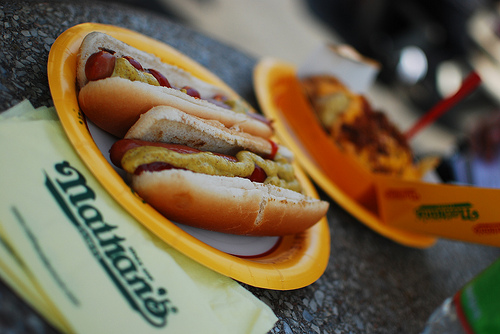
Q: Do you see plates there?
A: Yes, there is a plate.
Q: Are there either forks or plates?
A: Yes, there is a plate.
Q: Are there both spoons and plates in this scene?
A: No, there is a plate but no spoons.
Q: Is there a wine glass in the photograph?
A: No, there are no wine glasses.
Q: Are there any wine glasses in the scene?
A: No, there are no wine glasses.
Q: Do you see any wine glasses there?
A: No, there are no wine glasses.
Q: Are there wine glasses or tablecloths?
A: No, there are no wine glasses or tablecloths.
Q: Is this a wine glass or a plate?
A: This is a plate.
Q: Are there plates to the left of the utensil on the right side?
A: Yes, there is a plate to the left of the fork.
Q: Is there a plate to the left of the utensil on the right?
A: Yes, there is a plate to the left of the fork.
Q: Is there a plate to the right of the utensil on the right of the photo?
A: No, the plate is to the left of the fork.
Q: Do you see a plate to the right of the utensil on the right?
A: No, the plate is to the left of the fork.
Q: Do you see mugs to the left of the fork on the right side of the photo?
A: No, there is a plate to the left of the fork.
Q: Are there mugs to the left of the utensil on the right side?
A: No, there is a plate to the left of the fork.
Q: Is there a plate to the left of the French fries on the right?
A: Yes, there is a plate to the left of the fries.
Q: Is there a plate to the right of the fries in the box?
A: No, the plate is to the left of the French fries.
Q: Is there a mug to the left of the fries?
A: No, there is a plate to the left of the fries.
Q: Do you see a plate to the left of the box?
A: Yes, there is a plate to the left of the box.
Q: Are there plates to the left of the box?
A: Yes, there is a plate to the left of the box.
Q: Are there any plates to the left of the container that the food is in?
A: Yes, there is a plate to the left of the box.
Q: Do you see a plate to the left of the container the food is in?
A: Yes, there is a plate to the left of the box.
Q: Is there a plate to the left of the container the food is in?
A: Yes, there is a plate to the left of the box.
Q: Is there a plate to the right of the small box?
A: No, the plate is to the left of the box.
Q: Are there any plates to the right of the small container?
A: No, the plate is to the left of the box.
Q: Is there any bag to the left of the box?
A: No, there is a plate to the left of the box.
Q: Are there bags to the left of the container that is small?
A: No, there is a plate to the left of the box.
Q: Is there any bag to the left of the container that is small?
A: No, there is a plate to the left of the box.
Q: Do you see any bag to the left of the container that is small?
A: No, there is a plate to the left of the box.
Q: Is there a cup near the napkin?
A: No, there is a plate near the napkin.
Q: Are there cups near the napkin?
A: No, there is a plate near the napkin.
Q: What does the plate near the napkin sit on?
A: The plate sits on the table.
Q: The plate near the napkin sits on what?
A: The plate sits on the table.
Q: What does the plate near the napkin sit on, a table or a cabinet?
A: The plate sits on a table.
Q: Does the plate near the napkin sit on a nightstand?
A: No, the plate sits on the table.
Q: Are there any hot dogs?
A: Yes, there is a hot dog.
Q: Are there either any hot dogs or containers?
A: Yes, there is a hot dog.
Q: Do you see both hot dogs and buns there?
A: Yes, there are both a hot dog and a bun.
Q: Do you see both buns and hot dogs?
A: Yes, there are both a hot dog and a bun.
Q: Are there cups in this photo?
A: No, there are no cups.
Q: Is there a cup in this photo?
A: No, there are no cups.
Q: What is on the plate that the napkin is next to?
A: The hot dog is on the plate.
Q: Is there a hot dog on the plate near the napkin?
A: Yes, there is a hot dog on the plate.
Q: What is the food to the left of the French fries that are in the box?
A: The food is a hot dog.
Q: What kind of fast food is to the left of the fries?
A: The food is a hot dog.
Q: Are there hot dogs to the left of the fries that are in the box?
A: Yes, there is a hot dog to the left of the fries.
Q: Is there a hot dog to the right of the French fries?
A: No, the hot dog is to the left of the French fries.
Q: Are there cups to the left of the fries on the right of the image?
A: No, there is a hot dog to the left of the French fries.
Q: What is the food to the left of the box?
A: The food is a hot dog.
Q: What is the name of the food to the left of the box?
A: The food is a hot dog.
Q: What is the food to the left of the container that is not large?
A: The food is a hot dog.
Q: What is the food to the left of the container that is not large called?
A: The food is a hot dog.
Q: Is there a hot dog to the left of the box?
A: Yes, there is a hot dog to the left of the box.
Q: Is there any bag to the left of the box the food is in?
A: No, there is a hot dog to the left of the box.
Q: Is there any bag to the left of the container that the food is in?
A: No, there is a hot dog to the left of the box.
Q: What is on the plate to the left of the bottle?
A: The hot dog is on the plate.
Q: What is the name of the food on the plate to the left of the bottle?
A: The food is a hot dog.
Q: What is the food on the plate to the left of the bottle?
A: The food is a hot dog.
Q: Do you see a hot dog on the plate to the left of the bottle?
A: Yes, there is a hot dog on the plate.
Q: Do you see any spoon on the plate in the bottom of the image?
A: No, there is a hot dog on the plate.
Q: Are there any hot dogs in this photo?
A: Yes, there is a hot dog.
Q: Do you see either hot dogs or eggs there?
A: Yes, there is a hot dog.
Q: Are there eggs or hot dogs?
A: Yes, there is a hot dog.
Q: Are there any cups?
A: No, there are no cups.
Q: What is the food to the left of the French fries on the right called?
A: The food is a hot dog.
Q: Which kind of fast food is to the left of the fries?
A: The food is a hot dog.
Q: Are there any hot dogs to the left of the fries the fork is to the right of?
A: Yes, there is a hot dog to the left of the French fries.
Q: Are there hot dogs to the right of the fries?
A: No, the hot dog is to the left of the fries.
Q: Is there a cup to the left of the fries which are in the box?
A: No, there is a hot dog to the left of the fries.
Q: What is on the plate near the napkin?
A: The hot dog is on the plate.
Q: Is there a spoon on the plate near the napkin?
A: No, there is a hot dog on the plate.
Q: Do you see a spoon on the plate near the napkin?
A: No, there is a hot dog on the plate.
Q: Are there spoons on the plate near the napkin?
A: No, there is a hot dog on the plate.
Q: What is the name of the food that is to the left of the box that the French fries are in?
A: The food is a hot dog.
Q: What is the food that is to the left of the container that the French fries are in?
A: The food is a hot dog.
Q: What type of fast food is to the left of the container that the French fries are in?
A: The food is a hot dog.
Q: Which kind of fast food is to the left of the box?
A: The food is a hot dog.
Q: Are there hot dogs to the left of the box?
A: Yes, there is a hot dog to the left of the box.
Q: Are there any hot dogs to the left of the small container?
A: Yes, there is a hot dog to the left of the box.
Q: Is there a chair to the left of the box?
A: No, there is a hot dog to the left of the box.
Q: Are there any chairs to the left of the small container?
A: No, there is a hot dog to the left of the box.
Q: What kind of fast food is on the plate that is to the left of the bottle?
A: The food is a hot dog.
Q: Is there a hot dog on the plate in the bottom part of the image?
A: Yes, there is a hot dog on the plate.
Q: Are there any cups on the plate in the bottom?
A: No, there is a hot dog on the plate.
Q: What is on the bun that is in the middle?
A: The hot dog is on the bun.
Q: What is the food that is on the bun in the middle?
A: The food is a hot dog.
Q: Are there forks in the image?
A: Yes, there is a fork.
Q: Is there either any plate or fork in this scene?
A: Yes, there is a fork.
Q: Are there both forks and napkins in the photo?
A: Yes, there are both a fork and a napkin.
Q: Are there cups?
A: No, there are no cups.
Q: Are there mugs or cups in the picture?
A: No, there are no cups or mugs.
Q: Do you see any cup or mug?
A: No, there are no cups or mugs.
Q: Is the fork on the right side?
A: Yes, the fork is on the right of the image.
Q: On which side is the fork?
A: The fork is on the right of the image.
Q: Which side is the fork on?
A: The fork is on the right of the image.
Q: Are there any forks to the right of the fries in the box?
A: Yes, there is a fork to the right of the fries.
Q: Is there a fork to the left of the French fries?
A: No, the fork is to the right of the French fries.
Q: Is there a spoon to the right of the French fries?
A: No, there is a fork to the right of the French fries.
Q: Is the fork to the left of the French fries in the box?
A: No, the fork is to the right of the French fries.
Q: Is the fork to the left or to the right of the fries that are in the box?
A: The fork is to the right of the French fries.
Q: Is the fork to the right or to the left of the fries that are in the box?
A: The fork is to the right of the French fries.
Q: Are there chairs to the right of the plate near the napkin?
A: No, there is a fork to the right of the plate.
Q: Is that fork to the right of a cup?
A: No, the fork is to the right of the plate.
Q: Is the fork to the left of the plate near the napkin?
A: No, the fork is to the right of the plate.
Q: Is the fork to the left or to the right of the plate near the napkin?
A: The fork is to the right of the plate.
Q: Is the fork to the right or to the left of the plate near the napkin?
A: The fork is to the right of the plate.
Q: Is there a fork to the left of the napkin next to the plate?
A: No, the fork is to the right of the napkin.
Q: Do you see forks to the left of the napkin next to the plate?
A: No, the fork is to the right of the napkin.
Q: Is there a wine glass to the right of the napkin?
A: No, there is a fork to the right of the napkin.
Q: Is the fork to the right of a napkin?
A: Yes, the fork is to the right of a napkin.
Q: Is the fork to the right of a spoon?
A: No, the fork is to the right of a napkin.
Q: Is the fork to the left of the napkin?
A: No, the fork is to the right of the napkin.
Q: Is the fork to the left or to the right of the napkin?
A: The fork is to the right of the napkin.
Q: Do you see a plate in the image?
A: Yes, there is a plate.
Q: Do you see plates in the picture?
A: Yes, there is a plate.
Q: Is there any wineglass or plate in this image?
A: Yes, there is a plate.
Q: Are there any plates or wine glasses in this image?
A: Yes, there is a plate.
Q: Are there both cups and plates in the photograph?
A: No, there is a plate but no cups.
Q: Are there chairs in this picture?
A: No, there are no chairs.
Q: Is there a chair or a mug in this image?
A: No, there are no chairs or mugs.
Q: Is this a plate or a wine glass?
A: This is a plate.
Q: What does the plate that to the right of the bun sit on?
A: The plate sits on the table.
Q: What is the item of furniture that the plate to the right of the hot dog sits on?
A: The piece of furniture is a table.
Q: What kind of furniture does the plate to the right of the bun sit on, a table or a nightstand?
A: The plate sits on a table.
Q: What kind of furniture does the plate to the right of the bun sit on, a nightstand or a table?
A: The plate sits on a table.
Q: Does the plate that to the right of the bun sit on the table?
A: Yes, the plate sits on the table.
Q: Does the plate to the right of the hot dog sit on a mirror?
A: No, the plate sits on the table.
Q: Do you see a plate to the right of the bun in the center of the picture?
A: Yes, there is a plate to the right of the bun.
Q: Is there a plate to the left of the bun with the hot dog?
A: No, the plate is to the right of the bun.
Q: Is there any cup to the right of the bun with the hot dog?
A: No, there is a plate to the right of the bun.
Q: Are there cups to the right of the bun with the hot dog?
A: No, there is a plate to the right of the bun.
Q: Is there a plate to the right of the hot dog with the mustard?
A: Yes, there is a plate to the right of the hot dog.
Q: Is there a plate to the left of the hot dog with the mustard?
A: No, the plate is to the right of the hot dog.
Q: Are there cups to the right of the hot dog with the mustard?
A: No, there is a plate to the right of the hot dog.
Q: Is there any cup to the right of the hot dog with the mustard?
A: No, there is a plate to the right of the hot dog.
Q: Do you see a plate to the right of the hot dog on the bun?
A: Yes, there is a plate to the right of the hot dog.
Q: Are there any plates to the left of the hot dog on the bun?
A: No, the plate is to the right of the hot dog.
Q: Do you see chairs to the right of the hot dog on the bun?
A: No, there is a plate to the right of the hot dog.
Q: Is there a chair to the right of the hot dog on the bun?
A: No, there is a plate to the right of the hot dog.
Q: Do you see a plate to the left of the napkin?
A: No, the plate is to the right of the napkin.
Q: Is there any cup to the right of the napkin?
A: No, there is a plate to the right of the napkin.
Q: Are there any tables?
A: Yes, there is a table.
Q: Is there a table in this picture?
A: Yes, there is a table.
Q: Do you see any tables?
A: Yes, there is a table.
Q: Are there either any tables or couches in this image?
A: Yes, there is a table.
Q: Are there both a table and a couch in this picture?
A: No, there is a table but no couches.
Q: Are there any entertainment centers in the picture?
A: No, there are no entertainment centers.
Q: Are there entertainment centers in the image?
A: No, there are no entertainment centers.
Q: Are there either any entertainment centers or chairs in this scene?
A: No, there are no entertainment centers or chairs.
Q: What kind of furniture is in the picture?
A: The furniture is a table.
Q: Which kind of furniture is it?
A: The piece of furniture is a table.